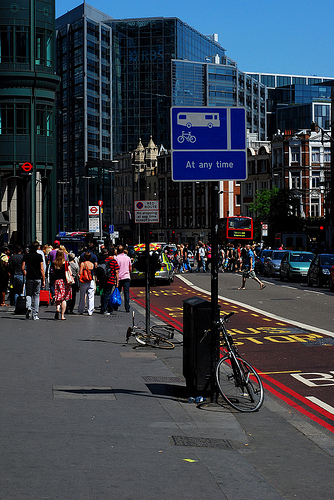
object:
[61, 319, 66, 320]
shoes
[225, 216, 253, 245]
bus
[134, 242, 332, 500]
street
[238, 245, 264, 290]
people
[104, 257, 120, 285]
shirt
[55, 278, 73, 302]
skirt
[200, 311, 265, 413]
bicycle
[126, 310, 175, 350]
bicycle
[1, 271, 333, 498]
ground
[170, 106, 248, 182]
blue sign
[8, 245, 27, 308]
man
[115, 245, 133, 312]
man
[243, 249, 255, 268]
blue shirt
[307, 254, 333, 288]
parked cars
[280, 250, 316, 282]
parked cars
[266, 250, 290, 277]
parked cars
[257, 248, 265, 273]
parked cars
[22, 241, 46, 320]
person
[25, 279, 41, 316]
jeans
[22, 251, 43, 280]
shirt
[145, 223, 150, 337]
black pole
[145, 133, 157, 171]
light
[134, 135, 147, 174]
light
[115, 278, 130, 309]
jeans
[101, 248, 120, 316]
person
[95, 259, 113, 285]
back pack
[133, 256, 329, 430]
road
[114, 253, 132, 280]
shirt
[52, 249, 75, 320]
woman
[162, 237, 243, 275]
people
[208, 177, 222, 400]
street pole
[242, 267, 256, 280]
shorts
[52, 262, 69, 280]
blouse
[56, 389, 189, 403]
shadow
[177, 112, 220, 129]
buses/bikes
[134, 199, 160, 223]
sign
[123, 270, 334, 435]
strip